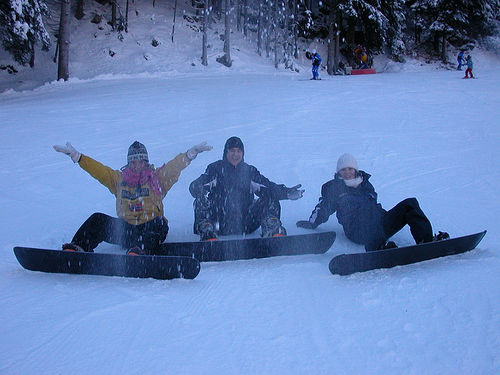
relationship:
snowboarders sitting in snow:
[291, 150, 448, 251] [8, 82, 499, 374]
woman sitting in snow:
[61, 136, 207, 249] [8, 82, 499, 374]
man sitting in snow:
[191, 137, 300, 238] [8, 82, 499, 374]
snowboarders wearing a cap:
[291, 150, 448, 251] [333, 151, 361, 174]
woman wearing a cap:
[61, 136, 207, 249] [126, 136, 146, 155]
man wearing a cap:
[191, 137, 300, 238] [217, 134, 246, 145]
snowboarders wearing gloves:
[291, 150, 448, 251] [300, 214, 319, 231]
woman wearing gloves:
[61, 136, 207, 249] [54, 131, 217, 169]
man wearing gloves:
[191, 137, 300, 238] [195, 187, 306, 207]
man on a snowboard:
[191, 137, 300, 238] [156, 233, 332, 257]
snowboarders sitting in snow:
[12, 130, 493, 287] [8, 82, 499, 374]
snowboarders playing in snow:
[12, 130, 493, 287] [8, 82, 499, 374]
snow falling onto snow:
[12, 8, 401, 80] [8, 82, 499, 374]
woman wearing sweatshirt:
[61, 136, 207, 249] [75, 152, 191, 221]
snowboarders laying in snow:
[291, 150, 448, 251] [8, 82, 499, 374]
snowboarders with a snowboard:
[291, 150, 448, 251] [330, 224, 486, 278]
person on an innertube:
[351, 46, 370, 65] [350, 69, 376, 77]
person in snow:
[351, 46, 370, 65] [8, 82, 499, 374]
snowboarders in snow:
[12, 130, 493, 287] [8, 82, 499, 374]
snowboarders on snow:
[12, 130, 493, 287] [8, 82, 499, 374]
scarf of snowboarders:
[124, 165, 160, 194] [291, 150, 448, 251]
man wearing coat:
[191, 137, 300, 238] [194, 160, 286, 205]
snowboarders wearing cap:
[291, 150, 448, 251] [333, 151, 361, 174]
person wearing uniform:
[302, 45, 325, 83] [310, 54, 319, 67]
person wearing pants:
[458, 50, 477, 78] [463, 67, 476, 77]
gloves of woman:
[54, 131, 217, 169] [61, 136, 207, 249]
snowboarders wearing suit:
[291, 150, 448, 251] [317, 182, 433, 241]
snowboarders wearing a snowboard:
[291, 150, 448, 251] [330, 224, 486, 278]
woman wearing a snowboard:
[61, 136, 207, 249] [15, 242, 199, 282]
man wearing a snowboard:
[191, 137, 300, 238] [156, 233, 332, 257]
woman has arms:
[61, 136, 207, 249] [54, 137, 209, 197]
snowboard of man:
[156, 233, 332, 257] [191, 137, 300, 238]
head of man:
[222, 137, 245, 165] [191, 137, 300, 238]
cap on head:
[217, 134, 246, 145] [222, 137, 245, 165]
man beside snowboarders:
[191, 137, 300, 238] [291, 150, 448, 251]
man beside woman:
[191, 137, 300, 238] [61, 136, 207, 249]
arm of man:
[253, 171, 292, 201] [191, 137, 300, 238]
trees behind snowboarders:
[1, 2, 475, 79] [12, 130, 493, 287]